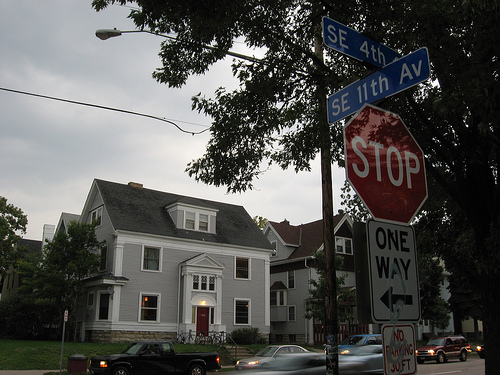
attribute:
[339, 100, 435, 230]
sign — octagon, red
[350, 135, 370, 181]
s — white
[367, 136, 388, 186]
t — white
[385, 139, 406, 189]
o — white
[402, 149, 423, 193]
p — white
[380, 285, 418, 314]
arrow — black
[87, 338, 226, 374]
truck — black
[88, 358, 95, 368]
headlight — on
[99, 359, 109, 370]
headlight — on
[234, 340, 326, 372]
car — gray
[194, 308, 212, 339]
door — red